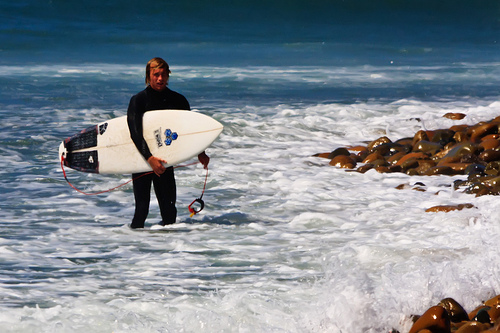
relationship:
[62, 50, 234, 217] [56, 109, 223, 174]
man carrying surfboard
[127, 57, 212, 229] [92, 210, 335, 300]
surfer standing surf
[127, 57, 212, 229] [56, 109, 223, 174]
surfer holding surfboard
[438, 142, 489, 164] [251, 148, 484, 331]
rock in surf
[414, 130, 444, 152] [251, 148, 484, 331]
rock in surf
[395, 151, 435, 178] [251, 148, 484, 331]
rock in surf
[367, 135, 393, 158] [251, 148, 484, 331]
rock in surf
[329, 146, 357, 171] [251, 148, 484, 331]
rock in surf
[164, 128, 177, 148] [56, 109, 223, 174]
design on surfboard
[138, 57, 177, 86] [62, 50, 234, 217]
hair on man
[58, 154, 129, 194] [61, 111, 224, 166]
rope on surfboard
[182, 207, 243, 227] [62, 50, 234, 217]
shadow on man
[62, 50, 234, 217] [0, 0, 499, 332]
man in water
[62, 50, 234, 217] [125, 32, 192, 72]
man has hair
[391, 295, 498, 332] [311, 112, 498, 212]
rocks near rocks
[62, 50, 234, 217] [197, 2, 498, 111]
man in water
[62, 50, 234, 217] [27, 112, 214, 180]
man holding surf board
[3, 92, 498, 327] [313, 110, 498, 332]
waves crashing on rocks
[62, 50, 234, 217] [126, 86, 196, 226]
man wearing wetsuit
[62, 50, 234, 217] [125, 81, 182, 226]
man has a wetsuit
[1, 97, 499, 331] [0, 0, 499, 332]
ripples in water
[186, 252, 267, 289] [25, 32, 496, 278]
ripples in water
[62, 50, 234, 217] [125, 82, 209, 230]
man in wet suit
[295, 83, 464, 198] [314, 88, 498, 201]
rocks are on shore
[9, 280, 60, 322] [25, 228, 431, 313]
ripples are on water